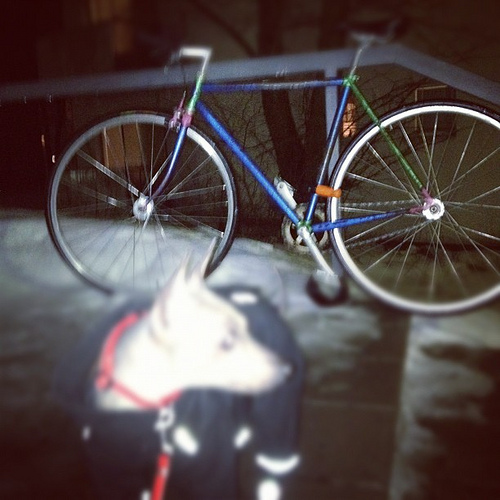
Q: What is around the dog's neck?
A: A collar.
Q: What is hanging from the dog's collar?
A: A leash.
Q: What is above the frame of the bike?
A: A seat.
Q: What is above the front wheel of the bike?
A: Handle bars.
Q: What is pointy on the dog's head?
A: Ears.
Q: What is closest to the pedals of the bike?
A: The chain.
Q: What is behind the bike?
A: A house.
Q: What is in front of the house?
A: A tree.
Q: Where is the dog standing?
A: On the sidewalk.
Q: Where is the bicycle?
A: Behind the dog.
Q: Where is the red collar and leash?
A: On the dog's neck.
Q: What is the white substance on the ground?
A: Snow.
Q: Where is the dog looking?
A: To his left.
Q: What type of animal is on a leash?
A: A dog.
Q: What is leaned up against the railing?
A: A bicycle.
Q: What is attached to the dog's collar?
A: A leash.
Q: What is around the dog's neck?
A: A collar.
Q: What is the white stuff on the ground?
A: Snow.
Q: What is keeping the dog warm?
A: Clothing.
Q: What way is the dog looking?
A: To the right.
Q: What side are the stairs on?
A: The right.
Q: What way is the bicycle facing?
A: To the left.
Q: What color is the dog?
A: White.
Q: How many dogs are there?
A: One.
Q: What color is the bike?
A: Blue.